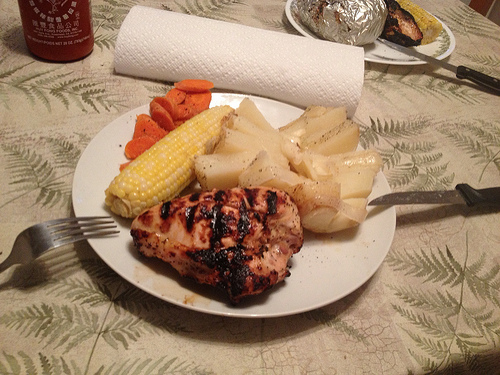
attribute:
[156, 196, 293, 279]
chicken — grilled, charred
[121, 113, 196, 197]
corn — yellow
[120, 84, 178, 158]
carrots — orange, cooked, round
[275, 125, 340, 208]
potato — cut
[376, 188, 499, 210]
knife — sharp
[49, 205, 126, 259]
fork — silver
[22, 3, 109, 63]
sauce — hot, red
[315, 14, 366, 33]
potato — wrapped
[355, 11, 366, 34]
foil — silver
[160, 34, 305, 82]
towel — white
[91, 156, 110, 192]
plate — round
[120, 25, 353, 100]
towels — white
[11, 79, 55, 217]
tablecloth — white, green